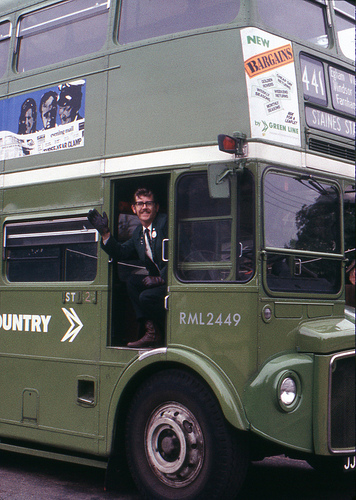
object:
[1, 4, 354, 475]
bus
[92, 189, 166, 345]
man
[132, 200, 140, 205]
glasses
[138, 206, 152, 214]
mustache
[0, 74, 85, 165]
ad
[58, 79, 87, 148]
person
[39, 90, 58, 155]
person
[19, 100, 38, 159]
person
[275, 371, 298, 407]
headlight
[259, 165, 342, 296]
windshield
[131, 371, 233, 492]
wheel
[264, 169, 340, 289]
window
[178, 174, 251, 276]
window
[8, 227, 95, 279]
window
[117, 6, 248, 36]
window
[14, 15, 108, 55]
window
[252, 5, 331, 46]
window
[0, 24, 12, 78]
window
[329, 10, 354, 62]
window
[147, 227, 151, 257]
tie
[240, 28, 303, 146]
ad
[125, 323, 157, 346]
boot